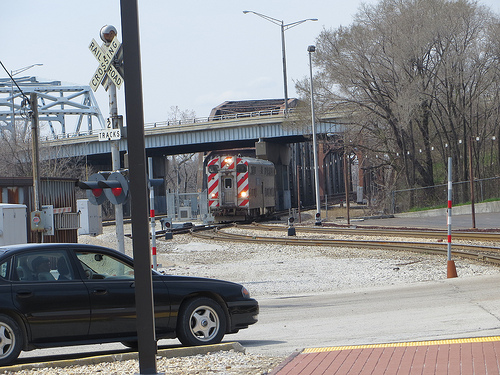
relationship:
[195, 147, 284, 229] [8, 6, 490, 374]
train in city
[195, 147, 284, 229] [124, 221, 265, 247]
train moving on tracks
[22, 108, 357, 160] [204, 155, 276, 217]
bridge over train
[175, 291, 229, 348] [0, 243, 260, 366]
tire on car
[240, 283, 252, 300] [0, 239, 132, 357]
headlight on car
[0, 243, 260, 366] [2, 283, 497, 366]
car driving on road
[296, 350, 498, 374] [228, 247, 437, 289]
brick on ground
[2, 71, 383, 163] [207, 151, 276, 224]
bridge over train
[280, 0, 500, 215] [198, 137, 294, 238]
trees beside train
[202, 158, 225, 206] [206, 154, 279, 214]
stripes on train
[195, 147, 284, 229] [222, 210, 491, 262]
train on tracks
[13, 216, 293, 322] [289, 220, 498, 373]
car stopped at crossing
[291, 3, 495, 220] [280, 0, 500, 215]
trees are in trees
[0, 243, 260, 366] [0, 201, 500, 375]
car on ground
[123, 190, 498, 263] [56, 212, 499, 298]
train tracks on ground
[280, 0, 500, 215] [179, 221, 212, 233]
trees on side of tracks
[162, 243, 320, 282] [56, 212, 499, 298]
rocks on ground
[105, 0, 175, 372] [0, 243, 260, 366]
pole beside car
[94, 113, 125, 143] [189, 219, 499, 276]
sign on train track